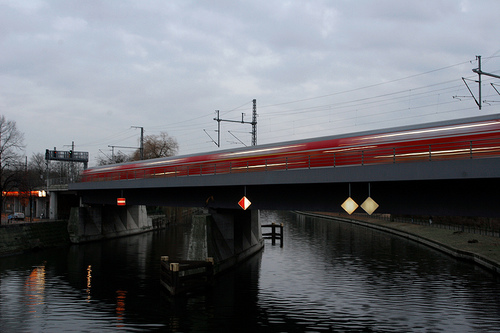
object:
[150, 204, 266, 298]
pillar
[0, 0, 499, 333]
photo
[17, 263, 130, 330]
lights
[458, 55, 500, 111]
pole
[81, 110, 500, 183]
red train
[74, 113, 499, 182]
moving quickly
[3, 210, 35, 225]
lot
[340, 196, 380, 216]
reflectors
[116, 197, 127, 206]
sign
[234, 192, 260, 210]
sign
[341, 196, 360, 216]
sign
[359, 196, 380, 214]
sign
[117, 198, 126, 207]
red square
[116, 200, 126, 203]
white stripe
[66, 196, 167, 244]
pillar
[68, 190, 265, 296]
supports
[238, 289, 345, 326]
ripples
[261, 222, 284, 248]
waterfencing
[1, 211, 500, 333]
water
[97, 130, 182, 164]
trees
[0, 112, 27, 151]
leaves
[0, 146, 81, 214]
front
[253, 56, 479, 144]
electrical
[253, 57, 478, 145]
lines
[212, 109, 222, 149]
poles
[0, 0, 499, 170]
sky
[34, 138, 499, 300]
bridge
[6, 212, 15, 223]
people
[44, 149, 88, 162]
light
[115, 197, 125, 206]
square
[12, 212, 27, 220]
vehicle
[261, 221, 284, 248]
fencing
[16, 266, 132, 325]
reflections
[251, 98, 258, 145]
pole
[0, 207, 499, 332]
canal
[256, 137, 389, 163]
blur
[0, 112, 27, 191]
tree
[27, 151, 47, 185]
tree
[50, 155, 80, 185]
tree